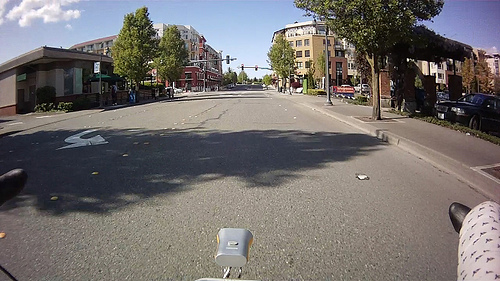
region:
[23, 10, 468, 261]
view of empty street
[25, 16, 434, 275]
view of empty road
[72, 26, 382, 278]
view from camera attached to bike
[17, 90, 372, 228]
large shadow of tree on road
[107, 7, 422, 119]
trees lining the street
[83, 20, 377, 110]
colorful buildings with many windows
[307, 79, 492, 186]
empty cement sidewalk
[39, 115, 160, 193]
left turn only lane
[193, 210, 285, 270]
headlight on front of bicycle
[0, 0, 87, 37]
white puffy clouds in blue sky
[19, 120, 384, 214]
shadow of tree on street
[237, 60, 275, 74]
traffic signals on post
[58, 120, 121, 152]
left turn arrow painted on road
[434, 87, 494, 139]
black truck in parking lot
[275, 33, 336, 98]
tall beige building on corner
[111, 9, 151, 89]
green leaves on trees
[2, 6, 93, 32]
puffy white cloud in blue sky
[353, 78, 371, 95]
white hatchback in parking spot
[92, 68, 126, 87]
green awning on building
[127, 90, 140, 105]
blue trash can on sidewalk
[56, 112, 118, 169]
White turning arrow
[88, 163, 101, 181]
Yellow road reflectors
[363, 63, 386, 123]
A brown tree trunk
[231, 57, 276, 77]
A stop light that is red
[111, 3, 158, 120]
A green tree with leafs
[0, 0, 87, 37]
A fluffy white cloud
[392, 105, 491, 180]
Part of a sidewalk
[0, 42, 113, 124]
A single story building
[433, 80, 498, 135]
A parked truck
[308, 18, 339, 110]
A street lamp that is off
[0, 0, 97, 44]
A white puffy cloud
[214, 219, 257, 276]
A light on a bike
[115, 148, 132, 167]
A yellow reflector bump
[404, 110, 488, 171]
Part of a side walk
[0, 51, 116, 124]
a building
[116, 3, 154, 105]
A green leafy tree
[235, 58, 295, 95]
A stop light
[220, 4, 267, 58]
A piece of blue sky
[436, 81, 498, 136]
Atruck that is parked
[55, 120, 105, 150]
the white arrow on the road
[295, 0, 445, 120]
the tree on the sidewalk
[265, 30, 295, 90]
the tree on the sidewalk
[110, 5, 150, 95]
the tree on the sidewalk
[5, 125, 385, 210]
the shadow on the road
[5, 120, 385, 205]
the shadow on the street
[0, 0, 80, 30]
the white clouds in the sky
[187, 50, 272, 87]
the traffic lights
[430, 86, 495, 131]
the dark parked car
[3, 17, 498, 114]
the buildings on the sides of the street